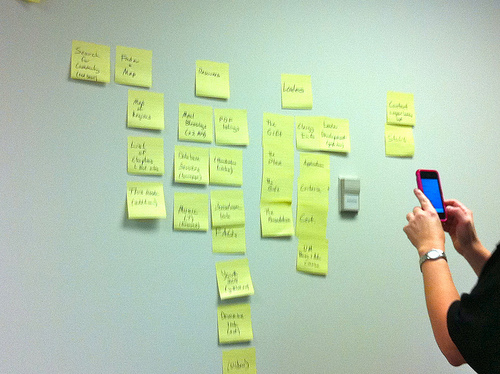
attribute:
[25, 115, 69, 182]
wall — white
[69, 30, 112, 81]
sticker — yellow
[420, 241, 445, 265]
watch — wrist watch, silver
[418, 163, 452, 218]
cellphone — mobile, pink, black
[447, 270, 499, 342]
tshirt — black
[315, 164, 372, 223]
thermostat — white, tan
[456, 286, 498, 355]
shirt — black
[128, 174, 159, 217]
paper — yellow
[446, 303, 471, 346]
sleeve — black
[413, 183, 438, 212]
finger — index, pointer